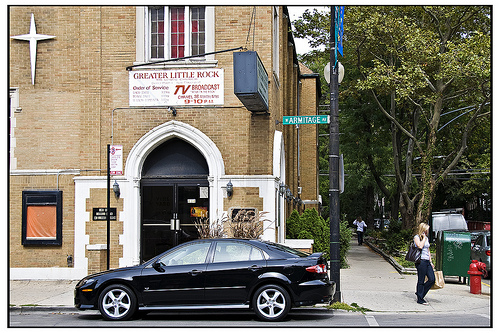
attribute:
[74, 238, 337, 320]
sedan — parked, black, four door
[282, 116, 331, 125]
sign — green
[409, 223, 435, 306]
woman — walking, walking away, talking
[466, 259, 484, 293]
hydrant — red, fire, bright red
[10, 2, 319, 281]
building — brick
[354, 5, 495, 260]
tree — large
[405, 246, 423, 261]
bag — large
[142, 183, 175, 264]
door — glass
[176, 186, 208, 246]
door — glass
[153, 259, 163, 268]
mirror — side view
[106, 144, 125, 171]
sign — parking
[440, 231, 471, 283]
mailbox — green